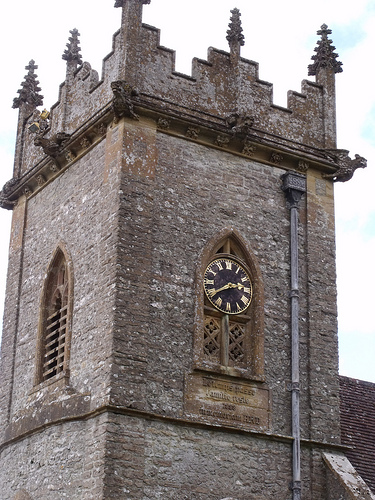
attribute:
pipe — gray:
[286, 196, 302, 498]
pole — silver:
[283, 168, 301, 499]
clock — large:
[199, 239, 271, 324]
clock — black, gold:
[196, 253, 258, 317]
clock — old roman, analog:
[197, 256, 254, 314]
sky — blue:
[326, 11, 367, 51]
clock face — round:
[203, 257, 252, 315]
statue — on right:
[202, 0, 250, 58]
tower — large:
[1, 4, 373, 495]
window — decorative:
[36, 228, 105, 406]